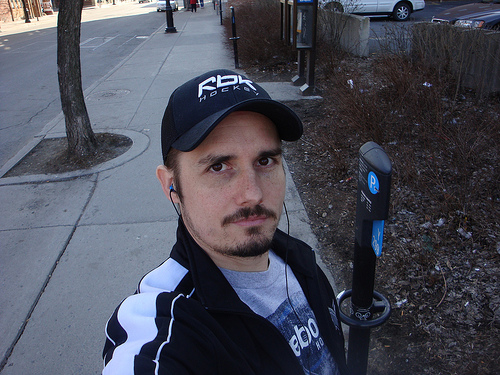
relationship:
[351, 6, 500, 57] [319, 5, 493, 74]
vehicles parked lot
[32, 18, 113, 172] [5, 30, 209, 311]
tree in sidewalk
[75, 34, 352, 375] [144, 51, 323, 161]
man wearing cap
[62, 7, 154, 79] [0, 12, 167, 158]
parking on street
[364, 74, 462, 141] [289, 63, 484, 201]
shrubs in wintertime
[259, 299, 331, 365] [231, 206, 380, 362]
shirt has logo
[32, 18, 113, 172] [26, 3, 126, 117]
tree has trunk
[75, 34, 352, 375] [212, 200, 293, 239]
man has lip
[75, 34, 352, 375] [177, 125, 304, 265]
man has face